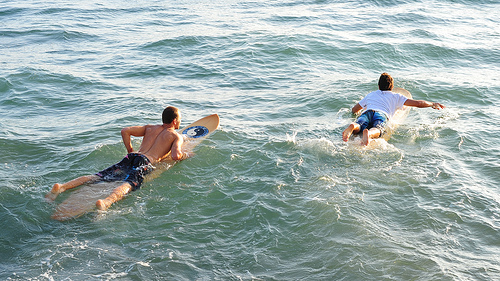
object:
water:
[0, 1, 499, 278]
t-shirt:
[357, 89, 406, 118]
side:
[437, 227, 476, 272]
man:
[354, 69, 405, 143]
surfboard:
[377, 87, 418, 158]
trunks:
[352, 107, 388, 135]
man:
[41, 97, 193, 233]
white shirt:
[354, 90, 409, 119]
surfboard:
[49, 112, 221, 222]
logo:
[181, 122, 208, 137]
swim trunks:
[97, 151, 157, 191]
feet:
[46, 181, 105, 216]